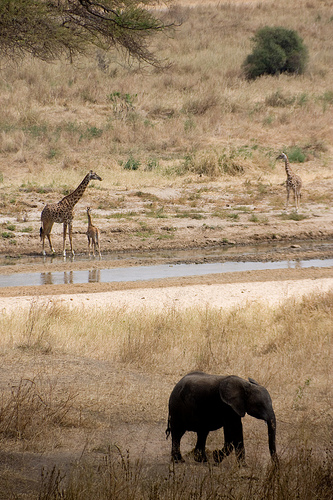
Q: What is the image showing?
A: It is showing a field.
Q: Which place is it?
A: It is a field.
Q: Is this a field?
A: Yes, it is a field.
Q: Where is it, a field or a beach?
A: It is a field.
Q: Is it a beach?
A: No, it is a field.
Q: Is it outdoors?
A: Yes, it is outdoors.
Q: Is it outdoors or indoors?
A: It is outdoors.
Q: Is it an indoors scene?
A: No, it is outdoors.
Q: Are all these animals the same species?
A: No, there are both giraffes and elephants.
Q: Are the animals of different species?
A: Yes, they are giraffes and elephants.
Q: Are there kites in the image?
A: No, there are no kites.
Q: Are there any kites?
A: No, there are no kites.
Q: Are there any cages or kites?
A: No, there are no kites or cages.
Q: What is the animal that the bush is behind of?
A: The animal is a giraffe.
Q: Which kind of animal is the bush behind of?
A: The bush is behind the giraffe.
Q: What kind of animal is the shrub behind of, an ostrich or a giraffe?
A: The shrub is behind a giraffe.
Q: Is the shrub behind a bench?
A: No, the shrub is behind the giraffe.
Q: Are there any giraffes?
A: Yes, there is a giraffe.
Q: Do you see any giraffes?
A: Yes, there is a giraffe.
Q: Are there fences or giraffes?
A: Yes, there is a giraffe.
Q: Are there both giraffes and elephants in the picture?
A: Yes, there are both a giraffe and an elephant.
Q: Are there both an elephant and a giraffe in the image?
A: Yes, there are both a giraffe and an elephant.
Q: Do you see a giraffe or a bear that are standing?
A: Yes, the giraffe is standing.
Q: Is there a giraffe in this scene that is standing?
A: Yes, there is a giraffe that is standing.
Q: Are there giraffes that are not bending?
A: Yes, there is a giraffe that is standing.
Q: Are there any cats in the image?
A: No, there are no cats.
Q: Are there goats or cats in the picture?
A: No, there are no cats or goats.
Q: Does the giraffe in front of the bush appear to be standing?
A: Yes, the giraffe is standing.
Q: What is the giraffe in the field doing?
A: The giraffe is standing.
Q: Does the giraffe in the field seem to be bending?
A: No, the giraffe is standing.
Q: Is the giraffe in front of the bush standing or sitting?
A: The giraffe is standing.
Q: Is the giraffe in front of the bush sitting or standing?
A: The giraffe is standing.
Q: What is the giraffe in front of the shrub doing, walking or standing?
A: The giraffe is standing.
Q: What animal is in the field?
A: The animal is a giraffe.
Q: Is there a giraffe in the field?
A: Yes, there is a giraffe in the field.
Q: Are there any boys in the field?
A: No, there is a giraffe in the field.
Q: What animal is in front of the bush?
A: The giraffe is in front of the shrub.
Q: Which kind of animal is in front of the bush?
A: The animal is a giraffe.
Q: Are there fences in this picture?
A: No, there are no fences.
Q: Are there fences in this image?
A: No, there are no fences.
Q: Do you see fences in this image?
A: No, there are no fences.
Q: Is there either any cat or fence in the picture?
A: No, there are no fences or cats.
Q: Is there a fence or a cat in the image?
A: No, there are no fences or cats.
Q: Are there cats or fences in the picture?
A: No, there are no fences or cats.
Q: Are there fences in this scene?
A: No, there are no fences.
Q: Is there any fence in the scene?
A: No, there are no fences.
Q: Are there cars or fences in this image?
A: No, there are no fences or cars.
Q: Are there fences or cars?
A: No, there are no fences or cars.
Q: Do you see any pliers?
A: No, there are no pliers.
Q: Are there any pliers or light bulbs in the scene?
A: No, there are no pliers or light bulbs.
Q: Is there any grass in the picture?
A: Yes, there is grass.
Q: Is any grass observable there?
A: Yes, there is grass.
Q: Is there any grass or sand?
A: Yes, there is grass.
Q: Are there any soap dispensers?
A: No, there are no soap dispensers.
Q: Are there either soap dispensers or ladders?
A: No, there are no soap dispensers or ladders.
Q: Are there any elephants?
A: Yes, there is an elephant.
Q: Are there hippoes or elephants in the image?
A: Yes, there is an elephant.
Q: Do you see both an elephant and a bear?
A: No, there is an elephant but no bears.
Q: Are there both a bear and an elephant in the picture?
A: No, there is an elephant but no bears.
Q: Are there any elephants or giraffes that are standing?
A: Yes, the elephant is standing.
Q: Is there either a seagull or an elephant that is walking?
A: Yes, the elephant is walking.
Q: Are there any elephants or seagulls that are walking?
A: Yes, the elephant is walking.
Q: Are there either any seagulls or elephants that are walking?
A: Yes, the elephant is walking.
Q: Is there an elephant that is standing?
A: Yes, there is an elephant that is standing.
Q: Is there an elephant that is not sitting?
A: Yes, there is an elephant that is standing.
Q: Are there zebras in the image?
A: No, there are no zebras.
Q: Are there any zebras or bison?
A: No, there are no zebras or bison.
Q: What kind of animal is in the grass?
A: The animal is an elephant.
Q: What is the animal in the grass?
A: The animal is an elephant.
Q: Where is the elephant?
A: The elephant is in the grass.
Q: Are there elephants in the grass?
A: Yes, there is an elephant in the grass.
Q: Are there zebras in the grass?
A: No, there is an elephant in the grass.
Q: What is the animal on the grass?
A: The animal is an elephant.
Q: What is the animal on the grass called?
A: The animal is an elephant.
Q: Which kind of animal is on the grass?
A: The animal is an elephant.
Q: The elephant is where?
A: The elephant is on the grass.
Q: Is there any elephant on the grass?
A: Yes, there is an elephant on the grass.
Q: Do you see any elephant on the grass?
A: Yes, there is an elephant on the grass.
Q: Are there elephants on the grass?
A: Yes, there is an elephant on the grass.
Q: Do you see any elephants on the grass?
A: Yes, there is an elephant on the grass.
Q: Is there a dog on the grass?
A: No, there is an elephant on the grass.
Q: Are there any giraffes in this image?
A: Yes, there is a giraffe.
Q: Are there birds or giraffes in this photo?
A: Yes, there is a giraffe.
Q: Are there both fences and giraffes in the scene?
A: No, there is a giraffe but no fences.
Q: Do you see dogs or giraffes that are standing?
A: Yes, the giraffe is standing.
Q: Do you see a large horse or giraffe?
A: Yes, there is a large giraffe.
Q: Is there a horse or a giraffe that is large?
A: Yes, the giraffe is large.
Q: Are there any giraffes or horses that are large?
A: Yes, the giraffe is large.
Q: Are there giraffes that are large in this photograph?
A: Yes, there is a large giraffe.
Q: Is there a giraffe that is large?
A: Yes, there is a giraffe that is large.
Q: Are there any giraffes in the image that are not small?
A: Yes, there is a large giraffe.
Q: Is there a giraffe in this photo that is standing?
A: Yes, there is a giraffe that is standing.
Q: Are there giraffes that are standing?
A: Yes, there is a giraffe that is standing.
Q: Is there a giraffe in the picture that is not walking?
A: Yes, there is a giraffe that is standing.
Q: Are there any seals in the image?
A: No, there are no seals.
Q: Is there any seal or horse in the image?
A: No, there are no seals or horses.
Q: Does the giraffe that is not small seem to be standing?
A: Yes, the giraffe is standing.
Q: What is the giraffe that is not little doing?
A: The giraffe is standing.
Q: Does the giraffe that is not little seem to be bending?
A: No, the giraffe is standing.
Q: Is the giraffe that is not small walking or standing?
A: The giraffe is standing.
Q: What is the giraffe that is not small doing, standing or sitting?
A: The giraffe is standing.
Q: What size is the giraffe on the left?
A: The giraffe is large.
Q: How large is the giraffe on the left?
A: The giraffe is large.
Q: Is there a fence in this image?
A: No, there are no fences.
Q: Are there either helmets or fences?
A: No, there are no fences or helmets.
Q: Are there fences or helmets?
A: No, there are no fences or helmets.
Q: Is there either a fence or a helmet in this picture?
A: No, there are no fences or helmets.